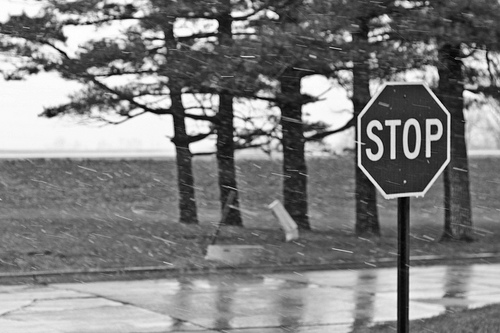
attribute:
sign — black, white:
[353, 71, 465, 209]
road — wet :
[166, 255, 393, 320]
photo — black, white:
[16, 15, 496, 328]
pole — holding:
[390, 197, 417, 327]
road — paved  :
[8, 269, 493, 330]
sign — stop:
[340, 71, 462, 224]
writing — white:
[366, 120, 439, 162]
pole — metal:
[361, 195, 427, 325]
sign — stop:
[347, 77, 459, 206]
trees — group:
[226, 72, 328, 214]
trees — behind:
[168, 69, 330, 228]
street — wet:
[13, 250, 498, 331]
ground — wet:
[6, 144, 493, 331]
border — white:
[349, 78, 458, 199]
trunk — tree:
[163, 73, 349, 213]